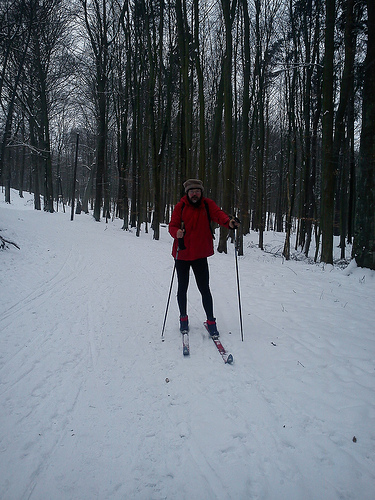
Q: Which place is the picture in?
A: It is at the field.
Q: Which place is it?
A: It is a field.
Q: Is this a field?
A: Yes, it is a field.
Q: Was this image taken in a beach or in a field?
A: It was taken at a field.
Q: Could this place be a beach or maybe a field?
A: It is a field.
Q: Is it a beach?
A: No, it is a field.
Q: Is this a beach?
A: No, it is a field.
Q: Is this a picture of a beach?
A: No, the picture is showing a field.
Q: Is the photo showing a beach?
A: No, the picture is showing a field.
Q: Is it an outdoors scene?
A: Yes, it is outdoors.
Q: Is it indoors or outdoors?
A: It is outdoors.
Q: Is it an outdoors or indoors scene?
A: It is outdoors.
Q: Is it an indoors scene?
A: No, it is outdoors.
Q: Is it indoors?
A: No, it is outdoors.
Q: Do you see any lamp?
A: No, there are no lamps.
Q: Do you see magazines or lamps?
A: No, there are no lamps or magazines.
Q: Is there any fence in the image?
A: No, there are no fences.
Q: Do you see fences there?
A: No, there are no fences.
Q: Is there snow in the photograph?
A: Yes, there is snow.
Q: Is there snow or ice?
A: Yes, there is snow.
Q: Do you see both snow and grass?
A: No, there is snow but no grass.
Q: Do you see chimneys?
A: No, there are no chimneys.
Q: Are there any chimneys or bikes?
A: No, there are no chimneys or bikes.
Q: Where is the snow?
A: The snow is on the ground.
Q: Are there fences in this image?
A: No, there are no fences.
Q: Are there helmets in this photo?
A: No, there are no helmets.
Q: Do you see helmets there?
A: No, there are no helmets.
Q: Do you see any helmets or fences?
A: No, there are no helmets or fences.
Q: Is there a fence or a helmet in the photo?
A: No, there are no helmets or fences.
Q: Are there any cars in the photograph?
A: No, there are no cars.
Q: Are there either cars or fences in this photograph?
A: No, there are no cars or fences.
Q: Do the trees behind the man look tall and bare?
A: Yes, the trees are tall and bare.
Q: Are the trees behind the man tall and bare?
A: Yes, the trees are tall and bare.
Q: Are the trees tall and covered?
A: No, the trees are tall but bare.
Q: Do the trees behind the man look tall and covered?
A: No, the trees are tall but bare.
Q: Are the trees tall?
A: Yes, the trees are tall.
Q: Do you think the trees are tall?
A: Yes, the trees are tall.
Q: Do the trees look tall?
A: Yes, the trees are tall.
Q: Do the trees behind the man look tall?
A: Yes, the trees are tall.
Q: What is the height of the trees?
A: The trees are tall.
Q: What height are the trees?
A: The trees are tall.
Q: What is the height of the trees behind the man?
A: The trees are tall.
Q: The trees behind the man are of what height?
A: The trees are tall.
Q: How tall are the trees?
A: The trees are tall.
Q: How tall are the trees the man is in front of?
A: The trees are tall.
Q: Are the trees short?
A: No, the trees are tall.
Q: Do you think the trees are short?
A: No, the trees are tall.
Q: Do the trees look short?
A: No, the trees are tall.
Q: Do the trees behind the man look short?
A: No, the trees are tall.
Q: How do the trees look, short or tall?
A: The trees are tall.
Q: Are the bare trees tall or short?
A: The trees are tall.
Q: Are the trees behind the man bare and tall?
A: Yes, the trees are bare and tall.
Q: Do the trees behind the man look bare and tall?
A: Yes, the trees are bare and tall.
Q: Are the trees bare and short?
A: No, the trees are bare but tall.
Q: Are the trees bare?
A: Yes, the trees are bare.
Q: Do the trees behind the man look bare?
A: Yes, the trees are bare.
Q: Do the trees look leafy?
A: No, the trees are bare.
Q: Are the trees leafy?
A: No, the trees are bare.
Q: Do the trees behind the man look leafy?
A: No, the trees are bare.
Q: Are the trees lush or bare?
A: The trees are bare.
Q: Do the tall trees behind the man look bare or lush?
A: The trees are bare.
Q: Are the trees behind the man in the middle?
A: Yes, the trees are behind the man.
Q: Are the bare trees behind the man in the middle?
A: Yes, the trees are behind the man.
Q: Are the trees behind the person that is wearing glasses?
A: Yes, the trees are behind the man.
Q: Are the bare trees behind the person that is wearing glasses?
A: Yes, the trees are behind the man.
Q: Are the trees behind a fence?
A: No, the trees are behind the man.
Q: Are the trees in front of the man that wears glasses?
A: No, the trees are behind the man.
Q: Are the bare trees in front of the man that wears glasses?
A: No, the trees are behind the man.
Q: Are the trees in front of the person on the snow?
A: No, the trees are behind the man.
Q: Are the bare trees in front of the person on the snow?
A: No, the trees are behind the man.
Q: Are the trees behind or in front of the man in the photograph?
A: The trees are behind the man.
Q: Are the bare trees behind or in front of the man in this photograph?
A: The trees are behind the man.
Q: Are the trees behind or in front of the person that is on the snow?
A: The trees are behind the man.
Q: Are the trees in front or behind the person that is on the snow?
A: The trees are behind the man.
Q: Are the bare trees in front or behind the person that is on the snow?
A: The trees are behind the man.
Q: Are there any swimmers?
A: No, there are no swimmers.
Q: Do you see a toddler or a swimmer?
A: No, there are no swimmers or toddlers.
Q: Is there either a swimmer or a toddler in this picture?
A: No, there are no swimmers or toddlers.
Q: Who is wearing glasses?
A: The man is wearing glasses.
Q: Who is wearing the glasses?
A: The man is wearing glasses.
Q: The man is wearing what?
A: The man is wearing glasses.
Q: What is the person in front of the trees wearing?
A: The man is wearing glasses.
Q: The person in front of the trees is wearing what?
A: The man is wearing glasses.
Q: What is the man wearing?
A: The man is wearing glasses.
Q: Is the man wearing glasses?
A: Yes, the man is wearing glasses.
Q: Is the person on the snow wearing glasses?
A: Yes, the man is wearing glasses.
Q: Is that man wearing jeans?
A: No, the man is wearing glasses.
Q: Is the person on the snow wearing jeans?
A: No, the man is wearing glasses.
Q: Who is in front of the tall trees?
A: The man is in front of the trees.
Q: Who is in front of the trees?
A: The man is in front of the trees.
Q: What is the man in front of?
A: The man is in front of the trees.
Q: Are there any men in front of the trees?
A: Yes, there is a man in front of the trees.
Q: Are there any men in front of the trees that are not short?
A: Yes, there is a man in front of the trees.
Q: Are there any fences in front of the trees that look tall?
A: No, there is a man in front of the trees.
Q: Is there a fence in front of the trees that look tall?
A: No, there is a man in front of the trees.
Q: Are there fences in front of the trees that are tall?
A: No, there is a man in front of the trees.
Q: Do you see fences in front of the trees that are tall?
A: No, there is a man in front of the trees.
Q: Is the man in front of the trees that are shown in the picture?
A: Yes, the man is in front of the trees.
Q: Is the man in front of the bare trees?
A: Yes, the man is in front of the trees.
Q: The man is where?
A: The man is on the snow.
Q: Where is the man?
A: The man is on the snow.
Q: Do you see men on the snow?
A: Yes, there is a man on the snow.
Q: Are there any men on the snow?
A: Yes, there is a man on the snow.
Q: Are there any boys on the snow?
A: No, there is a man on the snow.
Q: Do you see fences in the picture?
A: No, there are no fences.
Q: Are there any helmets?
A: No, there are no helmets.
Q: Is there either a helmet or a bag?
A: No, there are no helmets or bags.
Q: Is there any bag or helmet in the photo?
A: No, there are no helmets or bags.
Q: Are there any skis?
A: Yes, there are skis.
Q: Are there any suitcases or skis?
A: Yes, there are skis.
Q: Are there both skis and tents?
A: No, there are skis but no tents.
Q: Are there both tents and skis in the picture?
A: No, there are skis but no tents.